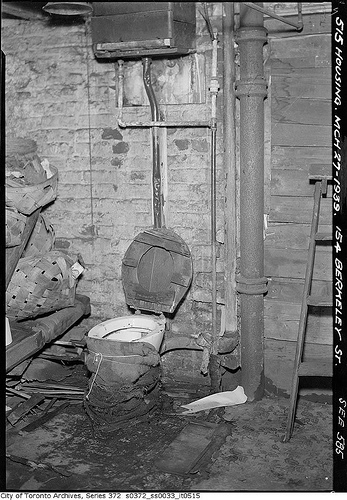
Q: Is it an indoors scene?
A: Yes, it is indoors.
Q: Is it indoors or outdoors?
A: It is indoors.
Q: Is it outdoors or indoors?
A: It is indoors.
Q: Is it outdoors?
A: No, it is indoors.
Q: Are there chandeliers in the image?
A: No, there are no chandeliers.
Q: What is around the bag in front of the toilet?
A: The cord is around the bag.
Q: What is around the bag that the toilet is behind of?
A: The cord is around the bag.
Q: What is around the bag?
A: The cord is around the bag.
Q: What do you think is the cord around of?
A: The cord is around the bag.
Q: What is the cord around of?
A: The cord is around the bag.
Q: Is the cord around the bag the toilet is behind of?
A: Yes, the cord is around the bag.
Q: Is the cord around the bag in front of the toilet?
A: Yes, the cord is around the bag.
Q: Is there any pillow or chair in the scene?
A: No, there are no pillows or chairs.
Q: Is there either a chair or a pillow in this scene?
A: No, there are no pillows or chairs.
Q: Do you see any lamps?
A: No, there are no lamps.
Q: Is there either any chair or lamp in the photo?
A: No, there are no lamps or chairs.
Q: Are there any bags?
A: Yes, there is a bag.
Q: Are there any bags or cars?
A: Yes, there is a bag.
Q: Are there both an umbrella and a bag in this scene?
A: No, there is a bag but no umbrellas.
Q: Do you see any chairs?
A: No, there are no chairs.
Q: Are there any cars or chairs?
A: No, there are no chairs or cars.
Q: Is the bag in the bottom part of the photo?
A: Yes, the bag is in the bottom of the image.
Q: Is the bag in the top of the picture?
A: No, the bag is in the bottom of the image.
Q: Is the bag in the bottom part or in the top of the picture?
A: The bag is in the bottom of the image.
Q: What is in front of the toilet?
A: The bag is in front of the toilet.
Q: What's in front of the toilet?
A: The bag is in front of the toilet.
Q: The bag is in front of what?
A: The bag is in front of the toilet.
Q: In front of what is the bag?
A: The bag is in front of the toilet.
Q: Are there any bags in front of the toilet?
A: Yes, there is a bag in front of the toilet.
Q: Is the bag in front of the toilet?
A: Yes, the bag is in front of the toilet.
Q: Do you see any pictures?
A: No, there are no pictures.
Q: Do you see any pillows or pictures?
A: No, there are no pictures or pillows.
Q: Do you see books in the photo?
A: No, there are no books.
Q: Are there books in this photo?
A: No, there are no books.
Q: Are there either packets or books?
A: No, there are no books or packets.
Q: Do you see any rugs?
A: No, there are no rugs.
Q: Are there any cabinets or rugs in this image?
A: No, there are no rugs or cabinets.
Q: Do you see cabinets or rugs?
A: No, there are no rugs or cabinets.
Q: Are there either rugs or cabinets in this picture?
A: No, there are no rugs or cabinets.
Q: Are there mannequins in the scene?
A: No, there are no mannequins.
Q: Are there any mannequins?
A: No, there are no mannequins.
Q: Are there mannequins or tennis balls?
A: No, there are no mannequins or tennis balls.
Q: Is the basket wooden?
A: Yes, the basket is wooden.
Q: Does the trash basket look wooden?
A: Yes, the basket is wooden.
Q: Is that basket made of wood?
A: Yes, the basket is made of wood.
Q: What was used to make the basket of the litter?
A: The basket is made of wood.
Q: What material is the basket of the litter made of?
A: The basket is made of wood.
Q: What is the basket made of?
A: The basket is made of wood.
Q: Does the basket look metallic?
A: No, the basket is wooden.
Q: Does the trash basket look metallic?
A: No, the basket is wooden.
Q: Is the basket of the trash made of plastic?
A: No, the basket is made of wood.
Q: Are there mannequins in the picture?
A: No, there are no mannequins.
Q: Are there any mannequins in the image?
A: No, there are no mannequins.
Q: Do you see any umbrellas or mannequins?
A: No, there are no mannequins or umbrellas.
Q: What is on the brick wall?
A: The pipe is on the wall.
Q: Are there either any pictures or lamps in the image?
A: No, there are no pictures or lamps.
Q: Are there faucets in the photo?
A: No, there are no faucets.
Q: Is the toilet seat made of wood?
A: Yes, the toilet seat is made of wood.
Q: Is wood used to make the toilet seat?
A: Yes, the toilet seat is made of wood.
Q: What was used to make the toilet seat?
A: The toilet seat is made of wood.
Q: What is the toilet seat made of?
A: The toilet seat is made of wood.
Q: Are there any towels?
A: No, there are no towels.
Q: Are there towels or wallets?
A: No, there are no towels or wallets.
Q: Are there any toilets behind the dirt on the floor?
A: Yes, there is a toilet behind the dirt.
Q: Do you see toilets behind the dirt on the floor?
A: Yes, there is a toilet behind the dirt.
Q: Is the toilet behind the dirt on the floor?
A: Yes, the toilet is behind the dirt.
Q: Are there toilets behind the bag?
A: Yes, there is a toilet behind the bag.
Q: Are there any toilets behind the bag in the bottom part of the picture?
A: Yes, there is a toilet behind the bag.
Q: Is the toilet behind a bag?
A: Yes, the toilet is behind a bag.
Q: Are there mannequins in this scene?
A: No, there are no mannequins.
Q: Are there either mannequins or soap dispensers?
A: No, there are no mannequins or soap dispensers.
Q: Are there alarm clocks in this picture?
A: No, there are no alarm clocks.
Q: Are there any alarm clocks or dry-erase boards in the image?
A: No, there are no alarm clocks or dry-erase boards.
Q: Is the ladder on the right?
A: Yes, the ladder is on the right of the image.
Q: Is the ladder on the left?
A: No, the ladder is on the right of the image.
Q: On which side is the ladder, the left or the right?
A: The ladder is on the right of the image.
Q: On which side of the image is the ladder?
A: The ladder is on the right of the image.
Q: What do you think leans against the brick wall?
A: The ladder leans against the wall.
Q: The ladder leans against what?
A: The ladder leans against the wall.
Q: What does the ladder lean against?
A: The ladder leans against the wall.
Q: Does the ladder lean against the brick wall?
A: Yes, the ladder leans against the wall.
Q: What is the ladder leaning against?
A: The ladder is leaning against the wall.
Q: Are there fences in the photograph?
A: No, there are no fences.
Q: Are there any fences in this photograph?
A: No, there are no fences.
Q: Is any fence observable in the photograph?
A: No, there are no fences.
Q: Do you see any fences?
A: No, there are no fences.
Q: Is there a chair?
A: No, there are no chairs.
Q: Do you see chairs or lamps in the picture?
A: No, there are no chairs or lamps.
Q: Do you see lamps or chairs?
A: No, there are no chairs or lamps.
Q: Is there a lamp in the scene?
A: No, there are no lamps.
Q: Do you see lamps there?
A: No, there are no lamps.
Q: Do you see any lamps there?
A: No, there are no lamps.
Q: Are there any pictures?
A: No, there are no pictures.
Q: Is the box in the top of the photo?
A: Yes, the box is in the top of the image.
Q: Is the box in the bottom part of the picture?
A: No, the box is in the top of the image.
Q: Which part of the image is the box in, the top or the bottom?
A: The box is in the top of the image.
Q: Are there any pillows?
A: No, there are no pillows.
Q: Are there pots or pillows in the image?
A: No, there are no pillows or pots.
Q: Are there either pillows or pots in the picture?
A: No, there are no pillows or pots.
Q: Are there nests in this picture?
A: No, there are no nests.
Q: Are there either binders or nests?
A: No, there are no nests or binders.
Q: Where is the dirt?
A: The dirt is on the floor.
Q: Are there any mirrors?
A: No, there are no mirrors.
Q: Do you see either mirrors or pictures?
A: No, there are no mirrors or pictures.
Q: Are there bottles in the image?
A: No, there are no bottles.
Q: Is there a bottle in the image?
A: No, there are no bottles.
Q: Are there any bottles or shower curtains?
A: No, there are no bottles or shower curtains.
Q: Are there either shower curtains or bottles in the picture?
A: No, there are no bottles or shower curtains.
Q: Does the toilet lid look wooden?
A: Yes, the toilet lid is wooden.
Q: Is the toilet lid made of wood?
A: Yes, the toilet lid is made of wood.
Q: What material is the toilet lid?
A: The toilet lid is made of wood.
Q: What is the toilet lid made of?
A: The toilet lid is made of wood.